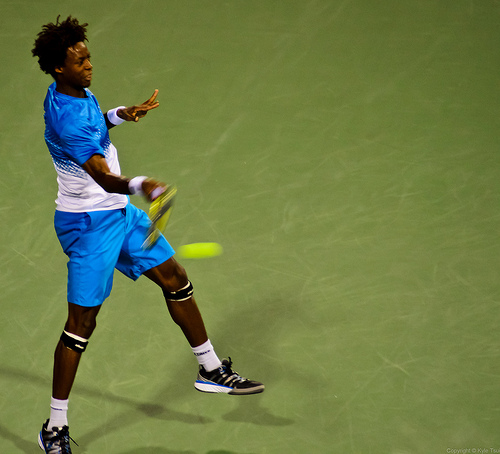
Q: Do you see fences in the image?
A: No, there are no fences.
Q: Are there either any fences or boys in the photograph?
A: No, there are no fences or boys.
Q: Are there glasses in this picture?
A: No, there are no glasses.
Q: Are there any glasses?
A: No, there are no glasses.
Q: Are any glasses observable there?
A: No, there are no glasses.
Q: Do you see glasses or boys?
A: No, there are no glasses or boys.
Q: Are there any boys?
A: No, there are no boys.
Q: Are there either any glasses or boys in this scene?
A: No, there are no boys or glasses.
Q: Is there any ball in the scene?
A: Yes, there is a ball.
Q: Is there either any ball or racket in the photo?
A: Yes, there is a ball.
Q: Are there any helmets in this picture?
A: No, there are no helmets.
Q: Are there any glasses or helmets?
A: No, there are no helmets or glasses.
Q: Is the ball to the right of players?
A: No, the ball is to the right of the drawers.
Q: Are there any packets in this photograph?
A: No, there are no packets.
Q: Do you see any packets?
A: No, there are no packets.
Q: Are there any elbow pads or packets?
A: No, there are no packets or elbow pads.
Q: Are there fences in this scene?
A: No, there are no fences.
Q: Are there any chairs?
A: No, there are no chairs.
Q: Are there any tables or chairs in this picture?
A: No, there are no chairs or tables.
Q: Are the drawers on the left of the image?
A: Yes, the drawers are on the left of the image.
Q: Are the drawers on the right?
A: No, the drawers are on the left of the image.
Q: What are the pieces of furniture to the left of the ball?
A: The pieces of furniture are drawers.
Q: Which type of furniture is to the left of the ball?
A: The pieces of furniture are drawers.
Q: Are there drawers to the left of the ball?
A: Yes, there are drawers to the left of the ball.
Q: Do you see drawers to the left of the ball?
A: Yes, there are drawers to the left of the ball.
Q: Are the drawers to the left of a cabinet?
A: No, the drawers are to the left of the ball.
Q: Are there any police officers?
A: No, there are no police officers.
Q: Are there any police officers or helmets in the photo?
A: No, there are no police officers or helmets.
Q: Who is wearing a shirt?
A: The man is wearing a shirt.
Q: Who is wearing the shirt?
A: The man is wearing a shirt.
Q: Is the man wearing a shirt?
A: Yes, the man is wearing a shirt.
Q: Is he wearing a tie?
A: No, the man is wearing a shirt.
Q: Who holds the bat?
A: The man holds the bat.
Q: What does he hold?
A: The man holds the bat.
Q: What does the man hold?
A: The man holds the bat.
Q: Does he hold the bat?
A: Yes, the man holds the bat.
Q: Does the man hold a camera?
A: No, the man holds the bat.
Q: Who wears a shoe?
A: The man wears a shoe.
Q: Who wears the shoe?
A: The man wears a shoe.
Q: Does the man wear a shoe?
A: Yes, the man wears a shoe.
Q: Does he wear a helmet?
A: No, the man wears a shoe.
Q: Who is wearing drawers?
A: The man is wearing drawers.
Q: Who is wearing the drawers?
A: The man is wearing drawers.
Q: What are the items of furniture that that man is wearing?
A: The pieces of furniture are drawers.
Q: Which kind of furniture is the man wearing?
A: The man is wearing drawers.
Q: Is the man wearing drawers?
A: Yes, the man is wearing drawers.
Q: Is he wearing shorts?
A: No, the man is wearing drawers.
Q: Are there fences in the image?
A: No, there are no fences.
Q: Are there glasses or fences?
A: No, there are no fences or glasses.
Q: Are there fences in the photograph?
A: No, there are no fences.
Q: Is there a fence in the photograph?
A: No, there are no fences.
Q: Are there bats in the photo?
A: Yes, there is a bat.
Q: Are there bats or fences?
A: Yes, there is a bat.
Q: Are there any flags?
A: No, there are no flags.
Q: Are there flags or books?
A: No, there are no flags or books.